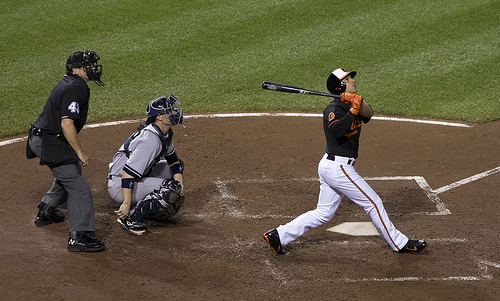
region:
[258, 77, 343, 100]
black bat in the batter's hands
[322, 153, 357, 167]
black belt in the white pants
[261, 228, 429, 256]
black and orange cleats on the batter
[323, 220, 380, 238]
white home plate in the dirt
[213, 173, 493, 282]
white batter's boxes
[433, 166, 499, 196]
white line on the field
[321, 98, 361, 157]
black jersey shirt on the batter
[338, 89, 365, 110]
orange batting gloves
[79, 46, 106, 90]
black face mask on the umpire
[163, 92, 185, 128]
silver and black face mask on the catcher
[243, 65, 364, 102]
The player is holding a bat.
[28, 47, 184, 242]
The umpire is behind the catcher.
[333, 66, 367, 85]
The player is wearing a helmet.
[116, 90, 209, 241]
The catcher is kneeling.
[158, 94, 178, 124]
The catcher is wearing a face mask.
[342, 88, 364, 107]
The player is wearing orange gloves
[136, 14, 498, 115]
The grass is green.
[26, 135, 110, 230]
The umpire is wearing gray pants.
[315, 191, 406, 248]
Home plate on the dirt.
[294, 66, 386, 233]
man in white pants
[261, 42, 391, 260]
man is swinging at ball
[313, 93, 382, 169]
man using orange gloves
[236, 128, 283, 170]
brown dirt with white lines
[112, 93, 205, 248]
catcher squatting behind batter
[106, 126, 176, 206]
catcher has on gray uniform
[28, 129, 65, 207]
umpire has gray pants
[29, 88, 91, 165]
umpire wearing black shirt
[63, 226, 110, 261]
umpire wearing black shoes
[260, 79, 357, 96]
black bat in hand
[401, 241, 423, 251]
black shoes of player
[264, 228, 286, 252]
black shoes of player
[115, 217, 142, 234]
black shoes of player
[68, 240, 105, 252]
black shoes of umpire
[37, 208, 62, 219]
black shoes of umpire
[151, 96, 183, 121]
black helmet of umpire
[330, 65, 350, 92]
black helmet of umpire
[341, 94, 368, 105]
orange gloves of player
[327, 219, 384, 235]
white base in dirt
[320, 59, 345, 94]
white and black helmet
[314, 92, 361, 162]
black and orange shirt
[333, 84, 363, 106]
batter has black gloves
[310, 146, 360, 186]
batter has black belt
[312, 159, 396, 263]
white and orange pants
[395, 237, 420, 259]
black and orange shoes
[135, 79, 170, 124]
catcher has black helmet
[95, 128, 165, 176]
black and grey shirt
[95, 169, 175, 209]
catcher has grey pants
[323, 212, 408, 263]
home plate is white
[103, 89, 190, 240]
catcher in grey uniform wearing a helmet and face grill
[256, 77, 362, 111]
black bat in hand of batter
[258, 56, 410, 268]
a man playing baseball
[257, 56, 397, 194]
a man swinging a bat